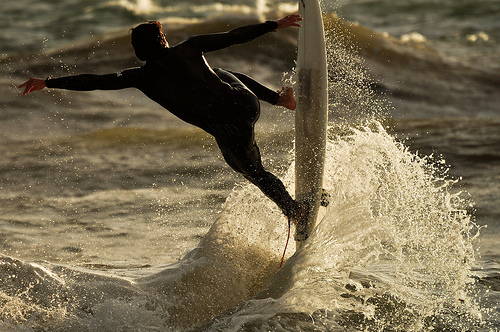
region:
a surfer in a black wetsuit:
[17, 0, 303, 222]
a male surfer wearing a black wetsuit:
[17, 13, 310, 226]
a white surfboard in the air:
[293, 0, 330, 247]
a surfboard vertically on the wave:
[17, 0, 331, 251]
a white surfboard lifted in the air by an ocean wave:
[0, 0, 497, 329]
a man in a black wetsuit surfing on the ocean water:
[15, 1, 475, 326]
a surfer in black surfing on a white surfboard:
[15, 0, 332, 245]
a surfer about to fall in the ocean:
[16, 0, 331, 250]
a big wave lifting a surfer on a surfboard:
[15, 0, 487, 329]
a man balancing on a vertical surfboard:
[15, 11, 308, 231]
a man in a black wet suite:
[112, 12, 287, 229]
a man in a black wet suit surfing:
[99, 7, 354, 269]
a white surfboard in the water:
[285, 3, 343, 267]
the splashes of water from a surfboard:
[342, 120, 471, 299]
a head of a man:
[125, 15, 177, 64]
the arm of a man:
[42, 63, 145, 97]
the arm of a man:
[204, 15, 276, 55]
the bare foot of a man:
[281, 80, 300, 110]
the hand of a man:
[16, 73, 44, 100]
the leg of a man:
[216, 142, 293, 227]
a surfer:
[12, 3, 359, 255]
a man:
[19, 4, 349, 266]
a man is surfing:
[19, 8, 391, 329]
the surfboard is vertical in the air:
[278, 1, 354, 258]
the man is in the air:
[17, 4, 337, 259]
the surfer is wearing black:
[33, 7, 317, 252]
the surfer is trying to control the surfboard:
[33, 9, 374, 256]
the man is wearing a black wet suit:
[7, 6, 342, 252]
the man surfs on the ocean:
[16, 3, 470, 320]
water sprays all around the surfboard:
[146, 132, 482, 329]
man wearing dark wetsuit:
[8, 8, 304, 249]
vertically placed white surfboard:
[293, 0, 329, 242]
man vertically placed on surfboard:
[13, 5, 332, 257]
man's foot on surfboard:
[248, 153, 324, 248]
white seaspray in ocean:
[333, 89, 480, 320]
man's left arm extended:
[14, 62, 141, 98]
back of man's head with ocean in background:
[93, 18, 175, 65]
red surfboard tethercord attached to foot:
[275, 209, 295, 275]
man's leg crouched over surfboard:
[208, 58, 295, 119]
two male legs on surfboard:
[208, 60, 316, 227]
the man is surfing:
[27, 0, 452, 318]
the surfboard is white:
[260, 0, 371, 280]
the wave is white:
[120, 155, 422, 322]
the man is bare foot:
[268, 53, 322, 237]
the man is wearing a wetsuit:
[0, 0, 310, 229]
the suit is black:
[14, 9, 290, 219]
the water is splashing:
[316, 87, 478, 309]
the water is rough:
[25, 2, 466, 139]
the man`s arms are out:
[15, 16, 364, 228]